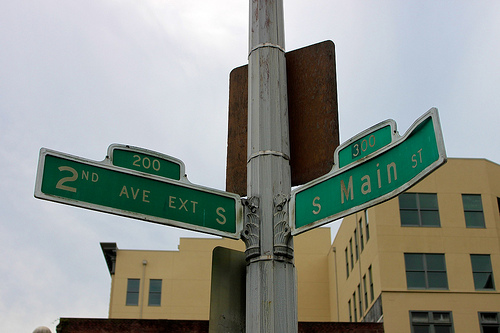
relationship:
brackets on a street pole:
[247, 41, 299, 261] [249, 4, 296, 332]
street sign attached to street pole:
[226, 38, 349, 199] [249, 4, 296, 332]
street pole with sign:
[249, 4, 296, 332] [35, 138, 237, 240]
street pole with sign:
[249, 4, 296, 332] [288, 102, 445, 222]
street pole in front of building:
[249, 4, 296, 332] [108, 138, 500, 332]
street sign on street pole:
[226, 38, 349, 199] [249, 4, 296, 332]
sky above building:
[4, 4, 498, 332] [108, 138, 500, 332]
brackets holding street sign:
[247, 41, 299, 261] [222, 38, 343, 199]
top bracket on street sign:
[248, 41, 284, 58] [226, 38, 349, 199]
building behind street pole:
[108, 138, 500, 332] [249, 4, 296, 332]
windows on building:
[125, 268, 164, 309] [108, 138, 500, 332]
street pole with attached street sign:
[249, 4, 296, 332] [222, 38, 343, 199]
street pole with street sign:
[249, 4, 296, 332] [222, 38, 343, 199]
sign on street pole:
[35, 138, 237, 240] [249, 4, 296, 332]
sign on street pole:
[288, 102, 445, 222] [249, 4, 296, 332]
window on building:
[458, 186, 489, 234] [108, 138, 500, 332]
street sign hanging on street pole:
[226, 38, 349, 199] [249, 4, 296, 332]